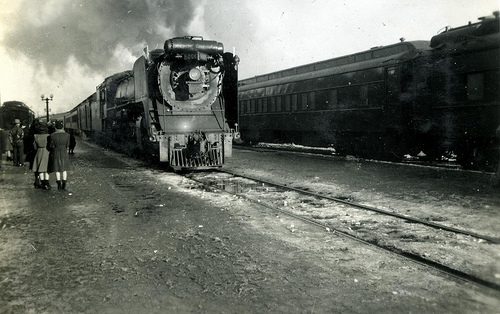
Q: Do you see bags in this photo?
A: No, there are no bags.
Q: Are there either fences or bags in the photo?
A: No, there are no bags or fences.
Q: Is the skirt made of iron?
A: Yes, the skirt is made of iron.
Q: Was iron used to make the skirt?
A: Yes, the skirt is made of iron.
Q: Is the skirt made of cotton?
A: No, the skirt is made of iron.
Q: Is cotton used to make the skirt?
A: No, the skirt is made of iron.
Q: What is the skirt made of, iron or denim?
A: The skirt is made of iron.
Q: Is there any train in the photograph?
A: Yes, there is a train.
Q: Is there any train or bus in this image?
A: Yes, there is a train.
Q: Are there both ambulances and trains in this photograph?
A: No, there is a train but no ambulances.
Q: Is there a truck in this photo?
A: No, there are no trucks.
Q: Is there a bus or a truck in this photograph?
A: No, there are no trucks or buses.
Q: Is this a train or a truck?
A: This is a train.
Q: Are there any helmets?
A: No, there are no helmets.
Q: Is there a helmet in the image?
A: No, there are no helmets.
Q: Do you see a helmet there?
A: No, there are no helmets.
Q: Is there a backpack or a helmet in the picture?
A: No, there are no helmets or backpacks.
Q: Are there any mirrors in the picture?
A: No, there are no mirrors.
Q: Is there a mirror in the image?
A: No, there are no mirrors.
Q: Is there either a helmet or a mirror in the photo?
A: No, there are no mirrors or helmets.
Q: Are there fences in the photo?
A: No, there are no fences.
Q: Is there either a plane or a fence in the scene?
A: No, there are no fences or airplanes.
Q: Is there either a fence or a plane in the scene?
A: No, there are no fences or airplanes.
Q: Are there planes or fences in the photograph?
A: No, there are no fences or planes.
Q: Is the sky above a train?
A: Yes, the sky is above a train.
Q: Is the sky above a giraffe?
A: No, the sky is above a train.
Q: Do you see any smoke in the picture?
A: Yes, there is smoke.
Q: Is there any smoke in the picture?
A: Yes, there is smoke.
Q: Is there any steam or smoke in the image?
A: Yes, there is smoke.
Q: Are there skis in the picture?
A: No, there are no skis.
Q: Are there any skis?
A: No, there are no skis.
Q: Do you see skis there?
A: No, there are no skis.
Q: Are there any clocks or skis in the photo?
A: No, there are no skis or clocks.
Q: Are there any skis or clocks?
A: No, there are no skis or clocks.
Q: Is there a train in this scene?
A: Yes, there is a train.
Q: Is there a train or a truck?
A: Yes, there is a train.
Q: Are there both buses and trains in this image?
A: No, there is a train but no buses.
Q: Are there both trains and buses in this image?
A: No, there is a train but no buses.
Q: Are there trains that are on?
A: Yes, there is a train that is on.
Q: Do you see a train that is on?
A: Yes, there is a train that is on.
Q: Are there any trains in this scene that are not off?
A: Yes, there is a train that is on.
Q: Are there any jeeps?
A: No, there are no jeeps.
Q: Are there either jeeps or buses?
A: No, there are no jeeps or buses.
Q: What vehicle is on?
A: The vehicle is a train.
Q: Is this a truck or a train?
A: This is a train.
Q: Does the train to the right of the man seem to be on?
A: Yes, the train is on.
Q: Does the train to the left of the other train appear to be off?
A: No, the train is on.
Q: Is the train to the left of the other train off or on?
A: The train is on.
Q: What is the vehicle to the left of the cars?
A: The vehicle is a train.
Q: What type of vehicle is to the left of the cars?
A: The vehicle is a train.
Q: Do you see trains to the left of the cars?
A: Yes, there is a train to the left of the cars.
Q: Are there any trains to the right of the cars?
A: No, the train is to the left of the cars.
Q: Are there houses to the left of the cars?
A: No, there is a train to the left of the cars.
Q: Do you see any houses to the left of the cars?
A: No, there is a train to the left of the cars.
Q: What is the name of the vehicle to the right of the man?
A: The vehicle is a train.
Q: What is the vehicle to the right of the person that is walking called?
A: The vehicle is a train.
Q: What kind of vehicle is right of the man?
A: The vehicle is a train.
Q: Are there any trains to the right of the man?
A: Yes, there is a train to the right of the man.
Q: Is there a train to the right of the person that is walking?
A: Yes, there is a train to the right of the man.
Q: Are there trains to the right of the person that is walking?
A: Yes, there is a train to the right of the man.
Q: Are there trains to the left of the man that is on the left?
A: No, the train is to the right of the man.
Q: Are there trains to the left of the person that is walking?
A: No, the train is to the right of the man.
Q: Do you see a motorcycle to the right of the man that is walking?
A: No, there is a train to the right of the man.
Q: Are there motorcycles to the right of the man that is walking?
A: No, there is a train to the right of the man.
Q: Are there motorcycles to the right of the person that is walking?
A: No, there is a train to the right of the man.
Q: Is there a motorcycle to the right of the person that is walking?
A: No, there is a train to the right of the man.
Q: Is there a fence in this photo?
A: No, there are no fences.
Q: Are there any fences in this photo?
A: No, there are no fences.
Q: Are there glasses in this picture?
A: No, there are no glasses.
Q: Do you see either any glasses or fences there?
A: No, there are no glasses or fences.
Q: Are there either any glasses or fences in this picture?
A: No, there are no glasses or fences.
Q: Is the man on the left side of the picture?
A: Yes, the man is on the left of the image.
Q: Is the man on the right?
A: No, the man is on the left of the image.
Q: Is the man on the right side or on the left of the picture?
A: The man is on the left of the image.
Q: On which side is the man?
A: The man is on the left of the image.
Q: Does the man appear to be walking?
A: Yes, the man is walking.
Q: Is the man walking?
A: Yes, the man is walking.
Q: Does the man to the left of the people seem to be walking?
A: Yes, the man is walking.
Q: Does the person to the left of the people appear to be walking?
A: Yes, the man is walking.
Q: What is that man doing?
A: The man is walking.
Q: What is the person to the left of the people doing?
A: The man is walking.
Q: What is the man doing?
A: The man is walking.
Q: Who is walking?
A: The man is walking.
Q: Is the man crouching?
A: No, the man is walking.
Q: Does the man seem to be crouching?
A: No, the man is walking.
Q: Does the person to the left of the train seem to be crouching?
A: No, the man is walking.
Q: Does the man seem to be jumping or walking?
A: The man is walking.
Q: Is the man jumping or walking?
A: The man is walking.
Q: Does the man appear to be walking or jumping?
A: The man is walking.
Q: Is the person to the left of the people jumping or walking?
A: The man is walking.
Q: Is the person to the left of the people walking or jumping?
A: The man is walking.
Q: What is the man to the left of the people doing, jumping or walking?
A: The man is walking.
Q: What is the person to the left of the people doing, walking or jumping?
A: The man is walking.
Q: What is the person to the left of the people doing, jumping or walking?
A: The man is walking.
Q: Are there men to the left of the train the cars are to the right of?
A: Yes, there is a man to the left of the train.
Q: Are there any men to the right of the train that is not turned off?
A: No, the man is to the left of the train.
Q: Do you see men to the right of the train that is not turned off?
A: No, the man is to the left of the train.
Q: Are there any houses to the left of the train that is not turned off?
A: No, there is a man to the left of the train.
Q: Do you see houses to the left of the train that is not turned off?
A: No, there is a man to the left of the train.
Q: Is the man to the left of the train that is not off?
A: Yes, the man is to the left of the train.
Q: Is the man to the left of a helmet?
A: No, the man is to the left of the train.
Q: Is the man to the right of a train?
A: No, the man is to the left of a train.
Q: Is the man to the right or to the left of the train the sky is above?
A: The man is to the left of the train.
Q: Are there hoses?
A: No, there are no hoses.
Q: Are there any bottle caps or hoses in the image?
A: No, there are no hoses or bottle caps.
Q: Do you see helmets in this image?
A: No, there are no helmets.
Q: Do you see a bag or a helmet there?
A: No, there are no helmets or bags.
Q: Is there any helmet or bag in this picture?
A: No, there are no helmets or bags.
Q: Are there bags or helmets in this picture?
A: No, there are no helmets or bags.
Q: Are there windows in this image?
A: Yes, there are windows.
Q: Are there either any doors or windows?
A: Yes, there are windows.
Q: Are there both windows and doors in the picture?
A: No, there are windows but no doors.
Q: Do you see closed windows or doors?
A: Yes, there are closed windows.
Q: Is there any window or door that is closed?
A: Yes, the windows are closed.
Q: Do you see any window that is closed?
A: Yes, there are closed windows.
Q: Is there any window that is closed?
A: Yes, there are windows that are closed.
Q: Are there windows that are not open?
A: Yes, there are closed windows.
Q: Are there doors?
A: No, there are no doors.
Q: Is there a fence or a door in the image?
A: No, there are no doors or fences.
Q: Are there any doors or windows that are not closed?
A: No, there are windows but they are closed.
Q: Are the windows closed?
A: Yes, the windows are closed.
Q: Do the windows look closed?
A: Yes, the windows are closed.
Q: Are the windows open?
A: No, the windows are closed.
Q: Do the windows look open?
A: No, the windows are closed.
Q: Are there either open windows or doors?
A: No, there are windows but they are closed.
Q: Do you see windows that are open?
A: No, there are windows but they are closed.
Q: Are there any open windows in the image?
A: No, there are windows but they are closed.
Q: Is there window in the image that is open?
A: No, there are windows but they are closed.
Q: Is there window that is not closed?
A: No, there are windows but they are closed.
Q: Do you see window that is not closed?
A: No, there are windows but they are closed.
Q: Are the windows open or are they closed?
A: The windows are closed.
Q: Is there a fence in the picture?
A: No, there are no fences.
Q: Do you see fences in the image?
A: No, there are no fences.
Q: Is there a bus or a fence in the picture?
A: No, there are no fences or buses.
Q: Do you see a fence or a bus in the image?
A: No, there are no fences or buses.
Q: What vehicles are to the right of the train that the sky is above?
A: The vehicles are cars.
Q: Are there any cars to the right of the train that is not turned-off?
A: Yes, there are cars to the right of the train.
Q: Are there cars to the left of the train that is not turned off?
A: No, the cars are to the right of the train.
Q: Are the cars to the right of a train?
A: Yes, the cars are to the right of a train.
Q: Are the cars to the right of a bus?
A: No, the cars are to the right of a train.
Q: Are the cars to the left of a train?
A: No, the cars are to the right of a train.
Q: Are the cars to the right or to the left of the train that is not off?
A: The cars are to the right of the train.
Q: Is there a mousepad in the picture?
A: No, there are no mouse pads.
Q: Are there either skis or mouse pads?
A: No, there are no mouse pads or skis.